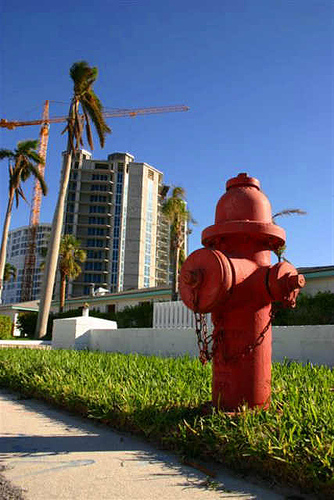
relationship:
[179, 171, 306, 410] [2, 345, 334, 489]
bolt on grass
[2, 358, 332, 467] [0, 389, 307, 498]
grass lining footpath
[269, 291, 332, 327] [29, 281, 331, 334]
shrubbery in front building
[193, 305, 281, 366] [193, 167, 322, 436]
chain on hydrant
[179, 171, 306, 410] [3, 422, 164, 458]
bolt has shadow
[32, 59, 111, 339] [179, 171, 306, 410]
palm tree near bolt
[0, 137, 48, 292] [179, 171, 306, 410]
palm tree near bolt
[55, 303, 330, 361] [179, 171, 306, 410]
wall behind bolt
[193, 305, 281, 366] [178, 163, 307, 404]
chain on firehydrant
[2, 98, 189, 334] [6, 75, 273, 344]
crane by building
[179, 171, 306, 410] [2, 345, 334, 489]
bolt in grass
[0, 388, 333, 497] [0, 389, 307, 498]
sun shining on footpath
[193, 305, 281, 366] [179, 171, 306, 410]
chain on bolt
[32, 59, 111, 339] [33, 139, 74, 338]
palm tree has trunk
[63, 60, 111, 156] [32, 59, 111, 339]
top of palm tree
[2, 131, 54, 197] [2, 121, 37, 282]
leaves on tree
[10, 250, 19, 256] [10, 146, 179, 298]
window on building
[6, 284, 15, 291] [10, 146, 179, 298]
window on building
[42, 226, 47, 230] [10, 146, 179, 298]
window on building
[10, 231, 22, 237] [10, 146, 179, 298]
window on building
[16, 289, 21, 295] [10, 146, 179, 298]
window on building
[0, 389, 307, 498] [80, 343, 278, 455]
footpath near grass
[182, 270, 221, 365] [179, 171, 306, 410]
chain on bolt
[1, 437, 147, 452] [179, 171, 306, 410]
shadow of bolt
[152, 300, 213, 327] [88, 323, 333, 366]
fence in front of wall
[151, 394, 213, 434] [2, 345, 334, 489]
shadow of grass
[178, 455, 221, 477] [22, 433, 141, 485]
bolt on walkway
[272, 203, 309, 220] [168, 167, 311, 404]
feather on hydrant